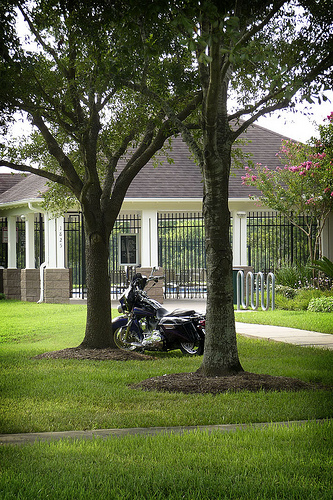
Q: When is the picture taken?
A: Daytime.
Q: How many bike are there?
A: One.